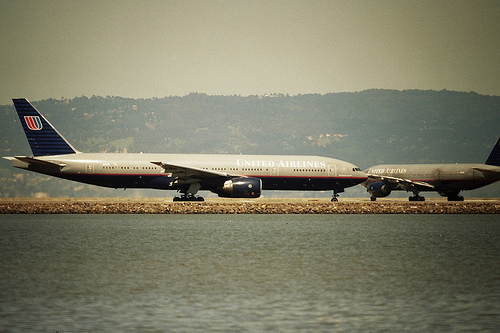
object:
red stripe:
[242, 174, 369, 179]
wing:
[148, 160, 248, 191]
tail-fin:
[11, 96, 78, 160]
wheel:
[173, 196, 180, 201]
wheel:
[188, 196, 197, 201]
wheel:
[197, 196, 204, 201]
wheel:
[331, 198, 338, 202]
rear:
[1, 98, 204, 202]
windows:
[294, 169, 296, 172]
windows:
[257, 168, 259, 171]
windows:
[236, 168, 238, 171]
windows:
[154, 167, 156, 170]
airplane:
[360, 136, 500, 202]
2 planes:
[1, 98, 500, 202]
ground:
[0, 197, 500, 204]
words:
[236, 159, 274, 168]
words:
[386, 168, 406, 173]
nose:
[338, 158, 368, 190]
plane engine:
[213, 175, 264, 198]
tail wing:
[13, 154, 67, 168]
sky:
[0, 0, 499, 106]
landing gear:
[172, 182, 204, 202]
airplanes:
[3, 88, 369, 208]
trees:
[477, 94, 500, 114]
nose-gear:
[331, 186, 345, 202]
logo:
[24, 116, 44, 131]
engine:
[368, 182, 392, 198]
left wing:
[362, 173, 434, 192]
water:
[0, 211, 499, 333]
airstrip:
[0, 196, 500, 208]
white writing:
[236, 158, 326, 167]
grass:
[0, 193, 500, 203]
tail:
[2, 95, 75, 175]